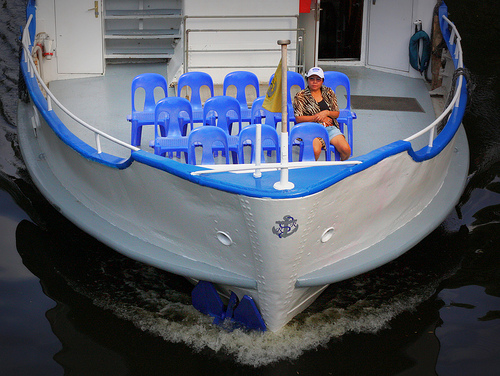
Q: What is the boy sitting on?
A: A blue plastic chair.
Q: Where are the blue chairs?
A: On the boat.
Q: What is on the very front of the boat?
A: A flag.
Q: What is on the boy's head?
A: A hat.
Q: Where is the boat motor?
A: In the water on the side of the boat.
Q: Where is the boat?
A: In the water.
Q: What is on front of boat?
A: A flag.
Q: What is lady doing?
A: Sitting in a chair.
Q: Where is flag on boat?
A: The front.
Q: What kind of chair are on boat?
A: Blue plastic.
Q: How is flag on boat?
A: A white pole.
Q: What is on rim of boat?
A: A rail.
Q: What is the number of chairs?
A: Twelve.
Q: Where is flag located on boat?
A: Front.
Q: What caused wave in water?
A: The propeller.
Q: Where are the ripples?
A: In front of the boat.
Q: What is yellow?
A: Flag.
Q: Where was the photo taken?
A: In front of a boat.